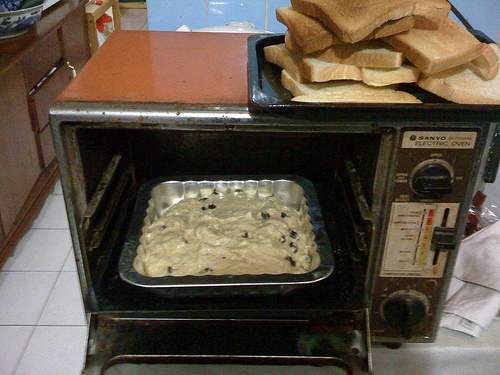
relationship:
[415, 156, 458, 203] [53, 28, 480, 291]
knob on front of microwave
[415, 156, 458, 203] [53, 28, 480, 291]
knob on microwave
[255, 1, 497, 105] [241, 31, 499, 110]
bread on top of pan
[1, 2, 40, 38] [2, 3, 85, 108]
bowl sitting on counter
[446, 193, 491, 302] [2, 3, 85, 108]
utensil on top of counter